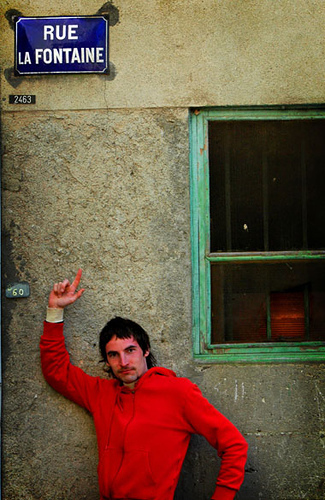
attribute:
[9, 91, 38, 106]
sign — small, black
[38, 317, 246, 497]
sweatshirt — orange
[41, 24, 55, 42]
letter r — large, white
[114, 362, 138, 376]
mustache — brown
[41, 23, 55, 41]
letter — white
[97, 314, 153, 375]
hair — brown, black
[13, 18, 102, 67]
letters — white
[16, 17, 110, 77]
sign — blue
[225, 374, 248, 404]
scratches — white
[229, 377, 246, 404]
marks — white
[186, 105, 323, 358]
window frame — wooden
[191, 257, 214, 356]
window pane — green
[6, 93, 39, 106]
rectangle — black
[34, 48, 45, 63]
letter f — white, large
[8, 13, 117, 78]
sign — blue , White letter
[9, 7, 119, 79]
sign — Black and white 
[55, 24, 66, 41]
letter — white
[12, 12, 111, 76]
sign — blue and white, blue, rectangle, white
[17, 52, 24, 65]
letter — white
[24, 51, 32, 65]
letter — white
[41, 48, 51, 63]
letter — white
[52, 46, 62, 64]
letter — white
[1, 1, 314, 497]
wall — dirty, stone, rock, gray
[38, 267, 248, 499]
man — standing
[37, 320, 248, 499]
jacket — red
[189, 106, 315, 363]
window — rectangular, closed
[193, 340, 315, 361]
window sill — green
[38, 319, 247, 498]
hoodie — red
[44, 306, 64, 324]
shirt cuff — white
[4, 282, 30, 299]
block — small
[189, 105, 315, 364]
frame — green, window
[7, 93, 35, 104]
block — black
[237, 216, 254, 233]
mark — white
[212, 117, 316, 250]
glass — clear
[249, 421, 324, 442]
crack — one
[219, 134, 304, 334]
bars — green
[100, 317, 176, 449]
man — one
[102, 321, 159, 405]
man — one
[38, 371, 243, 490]
jacket — red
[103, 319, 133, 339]
hair — brown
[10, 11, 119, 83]
sign — blue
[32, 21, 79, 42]
letters — white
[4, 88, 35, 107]
sign — small, black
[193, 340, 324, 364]
sill — green